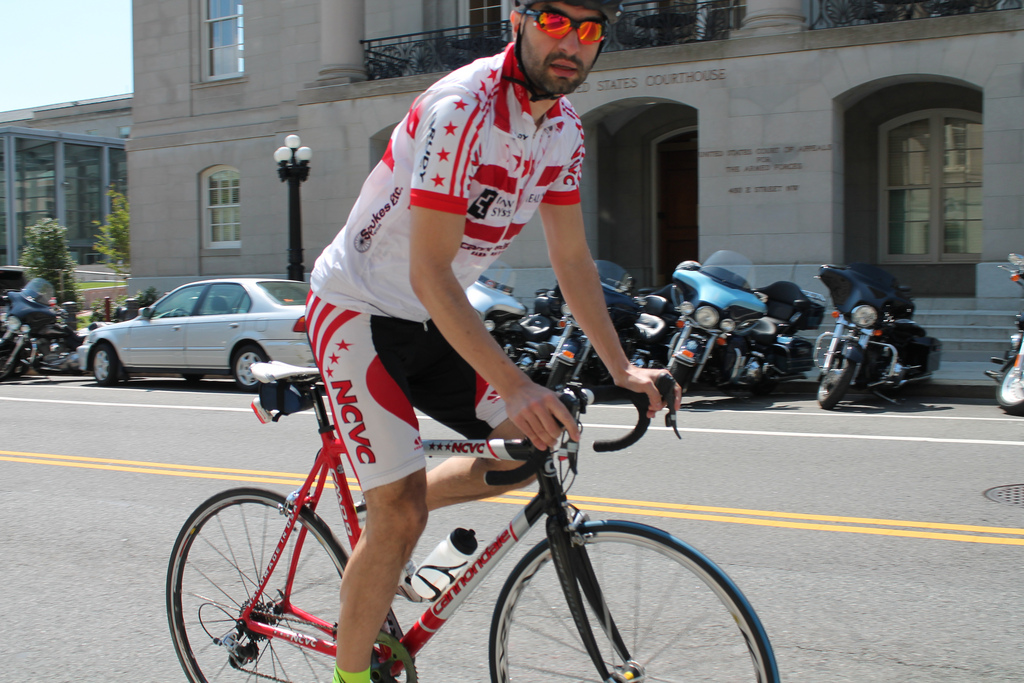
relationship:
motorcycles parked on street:
[674, 256, 947, 417] [687, 395, 988, 514]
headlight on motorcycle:
[690, 298, 725, 331] [666, 248, 826, 393]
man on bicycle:
[307, 4, 684, 677] [163, 371, 775, 678]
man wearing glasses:
[307, 4, 684, 677] [506, 4, 612, 50]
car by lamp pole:
[72, 272, 314, 404] [271, 131, 315, 281]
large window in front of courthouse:
[875, 110, 975, 266] [129, 0, 1024, 390]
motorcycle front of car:
[3, 276, 84, 382] [83, 276, 302, 387]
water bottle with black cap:
[406, 526, 475, 602] [448, 524, 475, 553]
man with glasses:
[307, 4, 684, 677] [506, 8, 612, 45]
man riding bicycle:
[307, 4, 684, 677] [162, 358, 773, 682]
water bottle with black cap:
[406, 526, 475, 602] [446, 524, 481, 553]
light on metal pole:
[285, 133, 301, 148] [279, 159, 310, 278]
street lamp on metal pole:
[296, 144, 314, 166] [279, 159, 310, 278]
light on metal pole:
[273, 146, 293, 162] [279, 159, 310, 278]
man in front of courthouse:
[307, 4, 684, 677] [122, 7, 1023, 390]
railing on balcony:
[344, 5, 723, 55] [359, 11, 714, 89]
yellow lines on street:
[5, 437, 1017, 559] [7, 372, 1021, 679]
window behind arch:
[880, 109, 993, 250] [818, 57, 1013, 300]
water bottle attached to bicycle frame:
[400, 519, 481, 612] [299, 409, 555, 651]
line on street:
[5, 435, 1021, 554] [7, 372, 1021, 679]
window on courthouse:
[200, 158, 253, 254] [129, 0, 1024, 390]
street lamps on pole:
[273, 124, 319, 177] [282, 186, 313, 301]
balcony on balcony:
[358, 0, 750, 82] [342, 24, 503, 79]